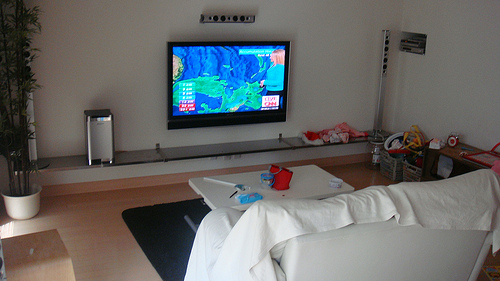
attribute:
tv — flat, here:
[165, 39, 292, 130]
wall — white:
[0, 2, 499, 188]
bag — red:
[269, 164, 293, 189]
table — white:
[189, 161, 355, 215]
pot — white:
[0, 180, 44, 221]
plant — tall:
[0, 2, 44, 198]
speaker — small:
[200, 12, 256, 24]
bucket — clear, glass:
[364, 137, 385, 169]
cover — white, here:
[182, 169, 499, 280]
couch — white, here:
[184, 165, 498, 280]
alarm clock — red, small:
[446, 135, 460, 148]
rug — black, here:
[122, 197, 211, 280]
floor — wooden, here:
[1, 157, 498, 279]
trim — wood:
[32, 150, 376, 198]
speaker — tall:
[367, 27, 393, 138]